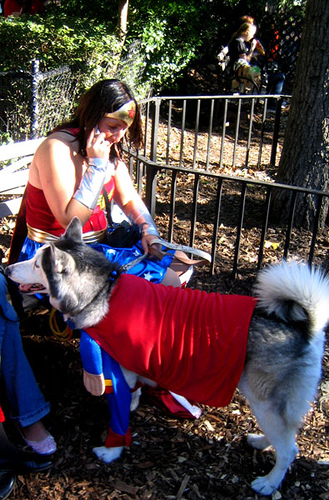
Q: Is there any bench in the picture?
A: Yes, there is a bench.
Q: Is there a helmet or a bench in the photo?
A: Yes, there is a bench.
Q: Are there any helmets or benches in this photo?
A: Yes, there is a bench.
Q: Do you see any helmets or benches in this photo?
A: Yes, there is a bench.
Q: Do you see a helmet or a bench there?
A: Yes, there is a bench.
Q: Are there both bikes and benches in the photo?
A: No, there is a bench but no bikes.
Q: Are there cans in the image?
A: No, there are no cans.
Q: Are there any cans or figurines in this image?
A: No, there are no cans or figurines.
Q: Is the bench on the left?
A: Yes, the bench is on the left of the image.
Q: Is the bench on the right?
A: No, the bench is on the left of the image.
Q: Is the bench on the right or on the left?
A: The bench is on the left of the image.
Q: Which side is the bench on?
A: The bench is on the left of the image.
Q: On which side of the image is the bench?
A: The bench is on the left of the image.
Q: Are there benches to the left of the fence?
A: Yes, there is a bench to the left of the fence.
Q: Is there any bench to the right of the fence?
A: No, the bench is to the left of the fence.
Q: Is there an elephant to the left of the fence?
A: No, there is a bench to the left of the fence.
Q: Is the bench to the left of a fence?
A: Yes, the bench is to the left of a fence.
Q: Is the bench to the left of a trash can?
A: No, the bench is to the left of a fence.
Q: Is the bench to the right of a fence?
A: No, the bench is to the left of a fence.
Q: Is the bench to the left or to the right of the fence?
A: The bench is to the left of the fence.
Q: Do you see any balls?
A: No, there are no balls.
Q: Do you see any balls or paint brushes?
A: No, there are no balls or paint brushes.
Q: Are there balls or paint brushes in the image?
A: No, there are no balls or paint brushes.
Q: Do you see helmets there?
A: No, there are no helmets.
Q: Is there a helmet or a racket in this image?
A: No, there are no helmets or rackets.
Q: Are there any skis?
A: No, there are no skis.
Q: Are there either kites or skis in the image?
A: No, there are no skis or kites.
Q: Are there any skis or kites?
A: No, there are no skis or kites.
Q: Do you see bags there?
A: No, there are no bags.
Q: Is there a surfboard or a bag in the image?
A: No, there are no bags or surfboards.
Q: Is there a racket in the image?
A: No, there are no rackets.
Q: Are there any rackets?
A: No, there are no rackets.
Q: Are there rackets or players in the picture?
A: No, there are no rackets or players.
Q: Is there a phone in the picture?
A: Yes, there is a phone.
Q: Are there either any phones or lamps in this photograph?
A: Yes, there is a phone.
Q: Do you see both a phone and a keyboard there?
A: No, there is a phone but no keyboards.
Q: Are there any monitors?
A: No, there are no monitors.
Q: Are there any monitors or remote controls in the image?
A: No, there are no monitors or remote controls.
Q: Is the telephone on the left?
A: Yes, the telephone is on the left of the image.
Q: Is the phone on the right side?
A: No, the phone is on the left of the image.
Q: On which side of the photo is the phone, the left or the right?
A: The phone is on the left of the image.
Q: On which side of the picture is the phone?
A: The phone is on the left of the image.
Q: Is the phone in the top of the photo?
A: Yes, the phone is in the top of the image.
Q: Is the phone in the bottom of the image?
A: No, the phone is in the top of the image.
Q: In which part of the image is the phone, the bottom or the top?
A: The phone is in the top of the image.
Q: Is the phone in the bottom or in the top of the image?
A: The phone is in the top of the image.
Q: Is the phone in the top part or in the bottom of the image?
A: The phone is in the top of the image.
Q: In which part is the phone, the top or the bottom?
A: The phone is in the top of the image.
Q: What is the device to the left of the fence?
A: The device is a phone.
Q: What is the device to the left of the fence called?
A: The device is a phone.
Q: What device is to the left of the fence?
A: The device is a phone.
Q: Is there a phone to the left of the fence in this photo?
A: Yes, there is a phone to the left of the fence.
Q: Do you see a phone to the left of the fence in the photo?
A: Yes, there is a phone to the left of the fence.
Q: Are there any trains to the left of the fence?
A: No, there is a phone to the left of the fence.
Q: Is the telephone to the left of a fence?
A: Yes, the telephone is to the left of a fence.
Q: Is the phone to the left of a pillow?
A: No, the phone is to the left of a fence.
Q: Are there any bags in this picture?
A: No, there are no bags.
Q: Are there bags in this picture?
A: No, there are no bags.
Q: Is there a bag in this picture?
A: No, there are no bags.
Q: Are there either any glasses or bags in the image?
A: No, there are no bags or glasses.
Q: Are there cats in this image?
A: No, there are no cats.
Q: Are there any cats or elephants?
A: No, there are no cats or elephants.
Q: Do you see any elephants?
A: No, there are no elephants.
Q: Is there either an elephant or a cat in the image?
A: No, there are no elephants or cats.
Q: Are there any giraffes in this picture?
A: No, there are no giraffes.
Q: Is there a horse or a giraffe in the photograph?
A: No, there are no giraffes or horses.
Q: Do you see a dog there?
A: Yes, there is a dog.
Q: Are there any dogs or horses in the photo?
A: Yes, there is a dog.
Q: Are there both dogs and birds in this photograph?
A: No, there is a dog but no birds.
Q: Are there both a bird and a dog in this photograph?
A: No, there is a dog but no birds.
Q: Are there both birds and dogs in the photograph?
A: No, there is a dog but no birds.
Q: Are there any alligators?
A: No, there are no alligators.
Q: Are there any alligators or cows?
A: No, there are no alligators or cows.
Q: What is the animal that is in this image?
A: The animal is a dog.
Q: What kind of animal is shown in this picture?
A: The animal is a dog.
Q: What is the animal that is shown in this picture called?
A: The animal is a dog.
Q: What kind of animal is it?
A: The animal is a dog.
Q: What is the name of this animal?
A: That is a dog.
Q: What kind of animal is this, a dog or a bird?
A: That is a dog.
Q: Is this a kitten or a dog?
A: This is a dog.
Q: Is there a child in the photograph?
A: Yes, there is a child.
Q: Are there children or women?
A: Yes, there is a child.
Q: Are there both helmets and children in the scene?
A: No, there is a child but no helmets.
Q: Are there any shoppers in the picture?
A: No, there are no shoppers.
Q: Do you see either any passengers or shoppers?
A: No, there are no shoppers or passengers.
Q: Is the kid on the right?
A: Yes, the kid is on the right of the image.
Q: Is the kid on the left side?
A: No, the kid is on the right of the image.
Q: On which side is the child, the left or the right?
A: The child is on the right of the image.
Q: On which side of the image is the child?
A: The child is on the right of the image.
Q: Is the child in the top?
A: Yes, the child is in the top of the image.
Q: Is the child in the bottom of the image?
A: No, the child is in the top of the image.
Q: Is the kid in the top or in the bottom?
A: The kid is in the top of the image.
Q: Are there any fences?
A: Yes, there is a fence.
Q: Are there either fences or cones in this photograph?
A: Yes, there is a fence.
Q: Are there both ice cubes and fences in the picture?
A: No, there is a fence but no ice cubes.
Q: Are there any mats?
A: No, there are no mats.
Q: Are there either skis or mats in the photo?
A: No, there are no mats or skis.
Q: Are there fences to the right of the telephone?
A: Yes, there is a fence to the right of the telephone.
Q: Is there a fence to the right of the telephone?
A: Yes, there is a fence to the right of the telephone.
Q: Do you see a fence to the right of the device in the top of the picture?
A: Yes, there is a fence to the right of the telephone.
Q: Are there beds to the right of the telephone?
A: No, there is a fence to the right of the telephone.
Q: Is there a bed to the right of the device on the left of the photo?
A: No, there is a fence to the right of the telephone.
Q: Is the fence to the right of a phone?
A: Yes, the fence is to the right of a phone.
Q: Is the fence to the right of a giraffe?
A: No, the fence is to the right of a phone.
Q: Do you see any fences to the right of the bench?
A: Yes, there is a fence to the right of the bench.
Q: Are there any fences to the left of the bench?
A: No, the fence is to the right of the bench.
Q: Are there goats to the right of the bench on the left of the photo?
A: No, there is a fence to the right of the bench.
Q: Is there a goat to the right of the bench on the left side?
A: No, there is a fence to the right of the bench.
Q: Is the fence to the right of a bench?
A: Yes, the fence is to the right of a bench.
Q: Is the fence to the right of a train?
A: No, the fence is to the right of a bench.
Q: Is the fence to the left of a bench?
A: No, the fence is to the right of a bench.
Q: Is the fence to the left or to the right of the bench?
A: The fence is to the right of the bench.